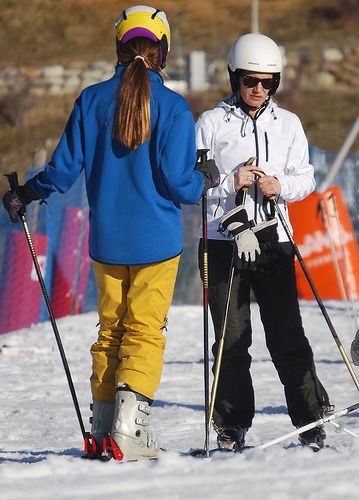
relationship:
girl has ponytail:
[5, 4, 222, 463] [109, 62, 170, 155]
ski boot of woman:
[215, 416, 250, 448] [189, 26, 340, 457]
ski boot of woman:
[288, 413, 327, 450] [189, 26, 340, 457]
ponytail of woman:
[88, 58, 154, 152] [82, 3, 181, 351]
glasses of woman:
[242, 75, 278, 89] [186, 29, 323, 451]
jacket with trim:
[23, 63, 213, 267] [87, 247, 184, 264]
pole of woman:
[3, 165, 118, 449] [111, 12, 213, 394]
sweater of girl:
[23, 65, 200, 267] [5, 4, 222, 463]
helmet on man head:
[227, 33, 282, 111] [224, 30, 282, 109]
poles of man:
[219, 171, 353, 377] [179, 13, 349, 498]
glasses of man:
[231, 75, 303, 95] [207, 42, 296, 222]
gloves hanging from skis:
[214, 175, 282, 256] [223, 149, 330, 344]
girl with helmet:
[193, 33, 330, 450] [216, 23, 281, 100]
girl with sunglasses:
[193, 33, 330, 450] [238, 65, 285, 104]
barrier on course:
[27, 218, 92, 276] [6, 238, 357, 368]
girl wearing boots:
[2, 5, 219, 462] [100, 387, 168, 462]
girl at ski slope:
[2, 5, 219, 462] [1, 298, 357, 498]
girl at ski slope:
[193, 33, 330, 450] [1, 298, 357, 498]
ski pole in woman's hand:
[197, 146, 210, 458] [200, 156, 222, 191]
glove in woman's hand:
[213, 204, 263, 262] [236, 158, 269, 189]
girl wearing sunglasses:
[193, 33, 330, 450] [239, 75, 282, 90]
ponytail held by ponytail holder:
[88, 47, 177, 145] [132, 51, 144, 65]